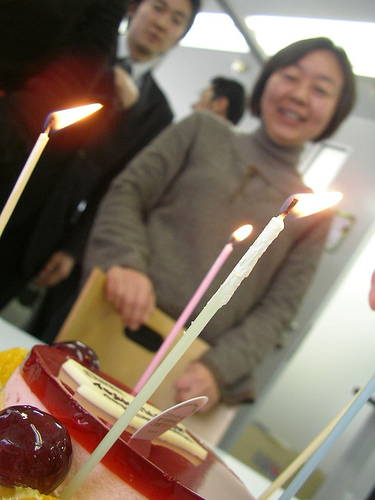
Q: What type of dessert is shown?
A: Cake.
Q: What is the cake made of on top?
A: Jello.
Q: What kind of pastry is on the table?
A: A cake.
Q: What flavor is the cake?
A: Strawberry.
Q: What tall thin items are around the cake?
A: Candles.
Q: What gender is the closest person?
A: Female.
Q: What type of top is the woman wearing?
A: A turtleneck.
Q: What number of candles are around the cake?
A: Five.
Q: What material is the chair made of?
A: Wood.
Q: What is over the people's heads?
A: Lights.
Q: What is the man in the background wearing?
A: A suit.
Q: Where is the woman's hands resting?
A: On the chair.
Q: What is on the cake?
A: Candles.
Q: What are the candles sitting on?
A: A cake.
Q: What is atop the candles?
A: Fire.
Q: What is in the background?
A: People looking at the cake.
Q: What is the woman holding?
A: A chair.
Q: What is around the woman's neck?
A: A necklace.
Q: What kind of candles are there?
A: Tall candles.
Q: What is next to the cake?
A: A decorative apple.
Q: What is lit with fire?
A: Candles.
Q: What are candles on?
A: Cake.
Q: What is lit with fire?
A: Candles.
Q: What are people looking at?
A: Cake and candles.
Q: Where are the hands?
A: Back of chaiar.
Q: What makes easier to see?
A: Lights in ceiling.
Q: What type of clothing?
A: Suit.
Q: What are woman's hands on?
A: Chair.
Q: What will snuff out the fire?
A: Wet fingers.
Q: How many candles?
A: Least 5.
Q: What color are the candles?
A: Pink, white and blue.